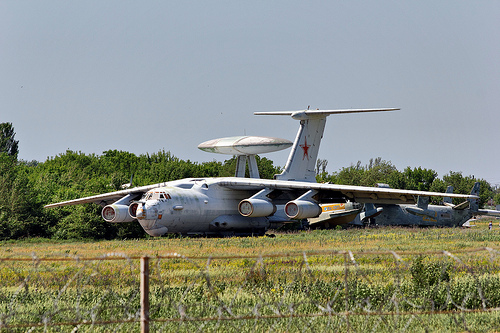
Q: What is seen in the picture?
A: Aeroplane.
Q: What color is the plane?
A: White.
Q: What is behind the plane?
A: Trees.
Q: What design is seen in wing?
A: Star.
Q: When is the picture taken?
A: Daytime.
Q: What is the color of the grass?
A: Brown.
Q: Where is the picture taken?
A: In a open field.